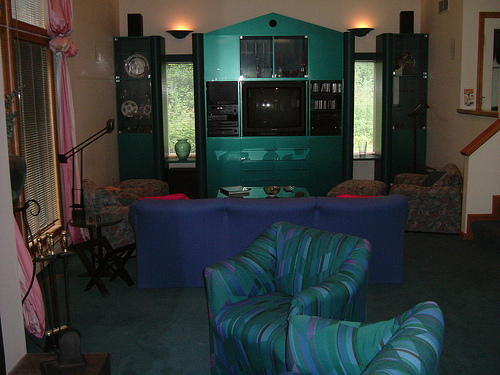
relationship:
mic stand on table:
[70, 137, 106, 224] [87, 211, 115, 230]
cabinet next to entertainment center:
[122, 132, 155, 172] [212, 23, 330, 173]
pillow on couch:
[147, 192, 186, 204] [171, 212, 255, 243]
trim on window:
[170, 57, 190, 66] [169, 84, 186, 146]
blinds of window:
[3, 34, 35, 96] [169, 84, 186, 146]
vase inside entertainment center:
[172, 136, 194, 158] [212, 23, 330, 173]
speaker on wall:
[124, 3, 146, 35] [85, 47, 106, 91]